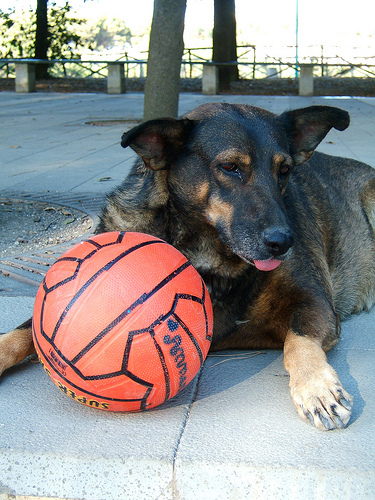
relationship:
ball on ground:
[27, 230, 214, 414] [7, 89, 374, 488]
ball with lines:
[27, 230, 214, 414] [30, 234, 214, 408]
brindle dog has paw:
[0, 100, 375, 433] [281, 338, 355, 433]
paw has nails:
[281, 338, 355, 433] [302, 390, 353, 429]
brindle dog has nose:
[0, 100, 375, 433] [259, 221, 297, 252]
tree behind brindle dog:
[143, 0, 188, 123] [0, 100, 375, 433]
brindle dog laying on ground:
[0, 100, 375, 433] [7, 89, 374, 488]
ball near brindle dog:
[31, 229, 214, 413] [0, 100, 375, 433]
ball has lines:
[27, 230, 214, 414] [30, 234, 214, 408]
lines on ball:
[30, 234, 214, 408] [27, 230, 214, 414]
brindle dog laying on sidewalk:
[2, 98, 374, 438] [0, 87, 375, 492]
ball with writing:
[31, 229, 214, 413] [165, 318, 190, 398]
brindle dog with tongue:
[0, 100, 375, 433] [251, 253, 288, 274]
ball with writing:
[27, 230, 214, 414] [165, 318, 190, 398]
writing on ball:
[165, 318, 190, 398] [27, 230, 214, 414]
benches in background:
[6, 57, 374, 97] [10, 0, 369, 167]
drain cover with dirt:
[5, 181, 118, 297] [4, 196, 92, 258]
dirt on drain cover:
[4, 196, 92, 258] [5, 181, 118, 297]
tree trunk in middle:
[145, 1, 188, 120] [87, 0, 262, 156]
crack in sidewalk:
[167, 355, 218, 493] [0, 87, 375, 492]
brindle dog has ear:
[0, 100, 375, 433] [124, 106, 203, 170]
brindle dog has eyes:
[0, 100, 375, 433] [218, 144, 295, 188]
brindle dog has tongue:
[0, 100, 375, 433] [251, 253, 288, 274]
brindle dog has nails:
[0, 100, 375, 433] [302, 390, 353, 429]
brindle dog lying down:
[0, 100, 375, 433] [13, 98, 373, 434]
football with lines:
[25, 230, 223, 409] [30, 234, 214, 408]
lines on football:
[30, 234, 214, 408] [25, 230, 223, 409]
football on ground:
[25, 230, 223, 409] [7, 89, 374, 488]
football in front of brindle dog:
[25, 230, 223, 409] [0, 100, 375, 433]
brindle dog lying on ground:
[0, 100, 375, 433] [7, 89, 374, 488]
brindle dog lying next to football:
[0, 100, 375, 433] [25, 230, 223, 409]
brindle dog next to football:
[0, 100, 375, 433] [25, 230, 223, 409]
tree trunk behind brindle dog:
[145, 1, 188, 120] [0, 100, 375, 433]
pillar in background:
[13, 62, 45, 92] [10, 0, 369, 167]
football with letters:
[25, 230, 223, 409] [53, 379, 116, 416]